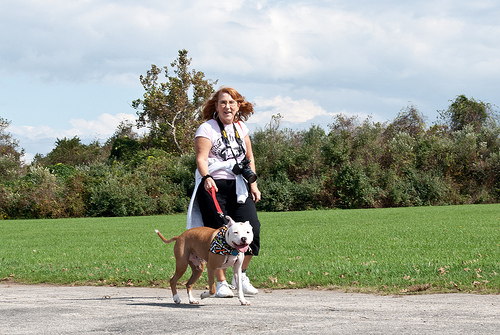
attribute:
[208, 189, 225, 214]
pink leash — short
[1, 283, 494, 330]
pathway — paved